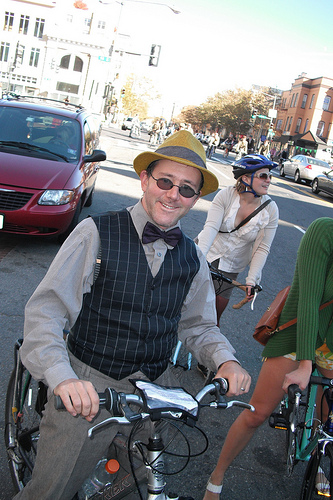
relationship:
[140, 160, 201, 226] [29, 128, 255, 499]
face of man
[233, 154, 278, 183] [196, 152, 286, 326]
helmet on woman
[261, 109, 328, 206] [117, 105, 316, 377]
car on road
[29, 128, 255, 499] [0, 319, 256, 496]
man riding bicycle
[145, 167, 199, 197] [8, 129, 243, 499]
sunglasses on man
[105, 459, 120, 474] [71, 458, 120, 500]
cap covering bottle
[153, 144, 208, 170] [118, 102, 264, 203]
band sewn on hat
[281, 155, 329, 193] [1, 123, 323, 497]
car parked on road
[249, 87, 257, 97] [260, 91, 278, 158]
light mounted on pole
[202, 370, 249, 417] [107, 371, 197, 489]
handlebar on bicycle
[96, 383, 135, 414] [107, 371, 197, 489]
handlebar on bicycle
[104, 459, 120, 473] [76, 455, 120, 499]
cap on bottle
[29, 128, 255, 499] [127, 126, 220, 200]
man wearing hat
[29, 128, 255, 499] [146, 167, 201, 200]
man wearing sunglasses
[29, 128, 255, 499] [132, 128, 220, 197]
man in hat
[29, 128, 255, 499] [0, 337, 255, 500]
man on bicycle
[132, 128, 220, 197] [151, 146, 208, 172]
hat with trim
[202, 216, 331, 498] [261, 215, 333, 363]
she wears green sweater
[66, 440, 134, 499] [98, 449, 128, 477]
water bottle with cap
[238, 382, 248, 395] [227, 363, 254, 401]
wedding ring on man's hand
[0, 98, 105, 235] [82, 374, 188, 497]
maroon car behind bikes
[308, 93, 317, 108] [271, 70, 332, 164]
window of building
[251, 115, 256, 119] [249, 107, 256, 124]
light on street light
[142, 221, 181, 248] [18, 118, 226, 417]
black bowtie on man